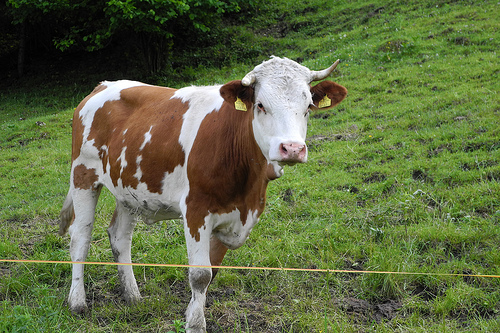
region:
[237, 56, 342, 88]
The horns of the cow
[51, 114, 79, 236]
The tail of the cow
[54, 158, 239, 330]
The legs of the cow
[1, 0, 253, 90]
The tree in the background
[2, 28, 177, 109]
The shadow under the tree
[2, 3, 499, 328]
The grassy hill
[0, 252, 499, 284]
The yellow string in front of cow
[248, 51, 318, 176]
The cow's white face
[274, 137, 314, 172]
The cow's pink nose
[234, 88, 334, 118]
The tags in the ear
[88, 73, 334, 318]
cow is brown and white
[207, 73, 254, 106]
cow has brown ears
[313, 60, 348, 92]
cow has white horn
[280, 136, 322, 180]
cow has pink nose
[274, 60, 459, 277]
grass is thick and green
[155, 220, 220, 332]
cow has white legs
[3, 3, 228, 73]
green trees behind cow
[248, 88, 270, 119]
cow has brown eyes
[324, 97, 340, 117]
yellow tag in cow's ear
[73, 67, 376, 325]
cow walks on grass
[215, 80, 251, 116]
yellow tag on cow's ear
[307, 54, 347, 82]
horn on the head of cow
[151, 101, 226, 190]
brown and white cow fur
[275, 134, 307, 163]
pink nose on cow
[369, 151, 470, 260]
green grass growing in field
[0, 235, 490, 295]
cord to contain the cow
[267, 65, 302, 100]
white tufts of fur on head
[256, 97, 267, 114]
dark eye of the cow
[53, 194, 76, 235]
end of tail hanging down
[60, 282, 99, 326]
foot in the grass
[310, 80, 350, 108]
an ear of a bull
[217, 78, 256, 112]
an ear of a bull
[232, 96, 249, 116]
a yellow tag in an ear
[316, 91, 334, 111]
a yellow tag in an ear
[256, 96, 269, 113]
an eye of a bull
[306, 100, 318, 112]
an eye of a bull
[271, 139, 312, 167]
the nose of a bull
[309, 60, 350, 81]
a horn of a bull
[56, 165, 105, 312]
the hind leg of a bull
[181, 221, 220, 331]
the front leg of a bull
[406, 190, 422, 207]
part of a surface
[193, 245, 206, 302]
leg of a cow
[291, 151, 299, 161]
nose of a cow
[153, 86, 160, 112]
body of a cow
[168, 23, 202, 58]
leaf of a plant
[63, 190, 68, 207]
tail of a cow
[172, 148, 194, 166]
white patch on a cow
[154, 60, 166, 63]
root of a tree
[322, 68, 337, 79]
horn of cow